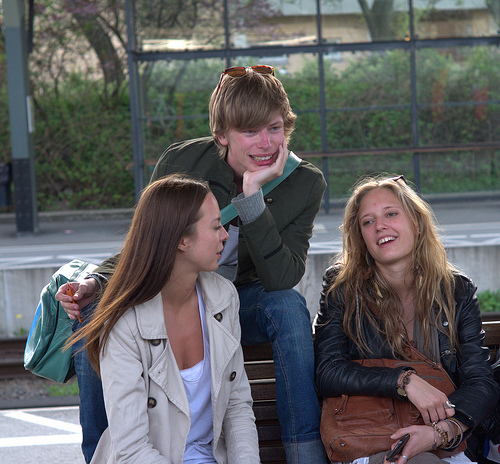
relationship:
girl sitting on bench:
[312, 171, 500, 462] [94, 321, 497, 461]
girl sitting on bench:
[86, 173, 261, 461] [94, 321, 497, 461]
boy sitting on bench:
[54, 66, 326, 463] [94, 321, 497, 461]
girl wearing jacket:
[312, 171, 500, 462] [316, 250, 491, 420]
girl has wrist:
[318, 174, 490, 461] [408, 412, 477, 454]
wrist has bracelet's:
[408, 412, 477, 454] [429, 417, 462, 442]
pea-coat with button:
[94, 273, 261, 462] [216, 304, 221, 320]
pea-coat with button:
[94, 273, 261, 462] [224, 362, 236, 384]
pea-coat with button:
[94, 273, 261, 462] [142, 370, 150, 380]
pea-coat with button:
[94, 273, 261, 462] [147, 395, 161, 412]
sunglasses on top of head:
[208, 65, 276, 79] [200, 66, 292, 186]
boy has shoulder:
[54, 61, 324, 462] [293, 150, 330, 205]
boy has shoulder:
[54, 61, 324, 462] [151, 127, 213, 182]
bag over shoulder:
[21, 257, 101, 389] [293, 150, 330, 205]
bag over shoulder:
[21, 257, 101, 389] [151, 127, 213, 182]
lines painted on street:
[24, 409, 73, 456] [39, 212, 116, 256]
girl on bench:
[77, 157, 257, 457] [107, 243, 468, 453]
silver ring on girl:
[444, 398, 457, 412] [318, 174, 490, 461]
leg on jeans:
[127, 63, 455, 408] [217, 274, 372, 435]